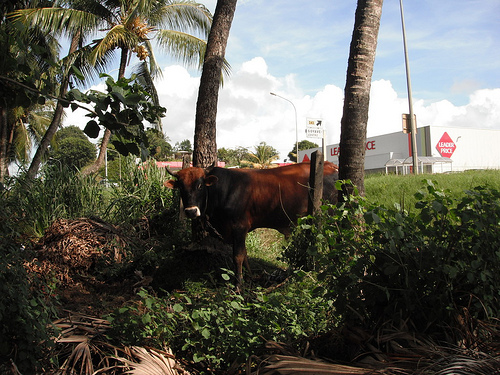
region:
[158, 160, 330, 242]
the cow between the palm trees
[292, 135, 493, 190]
the white building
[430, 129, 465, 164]
the sign on the building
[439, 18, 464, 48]
the clear blue sky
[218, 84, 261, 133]
the clouds in the sky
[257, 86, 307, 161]
the street light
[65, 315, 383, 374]
dead leaves in the under brush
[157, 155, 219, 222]
the head of the cow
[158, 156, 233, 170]
the horns on the cow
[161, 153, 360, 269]
the cow is brown and black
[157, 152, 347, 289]
this is a cow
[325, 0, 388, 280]
this is a tree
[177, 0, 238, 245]
this is a tree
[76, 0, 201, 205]
this is a tree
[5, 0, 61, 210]
this is a tree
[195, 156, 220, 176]
this a horn of a cow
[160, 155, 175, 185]
this a horn of a cow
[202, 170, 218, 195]
this an ear of a cow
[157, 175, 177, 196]
this an ear of a cow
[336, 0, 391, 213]
a palm tree trunk.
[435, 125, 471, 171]
a red road sign.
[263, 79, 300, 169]
a street light near a building.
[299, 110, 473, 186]
a semi truck trailer.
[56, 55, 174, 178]
a leafy green palm tree.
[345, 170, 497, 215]
a lush green hillside.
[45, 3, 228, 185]
a palm tree on a hillside.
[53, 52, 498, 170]
A sky full of clouds.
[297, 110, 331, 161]
a sign near a road.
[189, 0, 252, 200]
a palm tree trunk.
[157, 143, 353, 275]
brown bull with horns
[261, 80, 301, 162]
lamp post on side of street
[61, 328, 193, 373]
dried palm tree leaves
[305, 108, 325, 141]
road sign on side of street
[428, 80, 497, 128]
white clouds in the sky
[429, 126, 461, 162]
red diamond sign on side of building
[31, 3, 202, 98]
palm trees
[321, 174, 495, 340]
green leafy bushes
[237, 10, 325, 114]
blue sky with white clouds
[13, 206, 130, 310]
pile of dead leaves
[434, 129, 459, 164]
the sign is red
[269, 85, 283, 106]
the light is off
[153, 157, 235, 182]
the bull has horns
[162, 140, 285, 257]
the bull is brown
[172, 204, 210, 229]
the nose is black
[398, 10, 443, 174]
the pole metal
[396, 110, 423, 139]
the sign is square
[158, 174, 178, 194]
the bull has an ear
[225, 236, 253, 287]
the bull as a front leg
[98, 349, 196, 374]
the fern is brown and dry